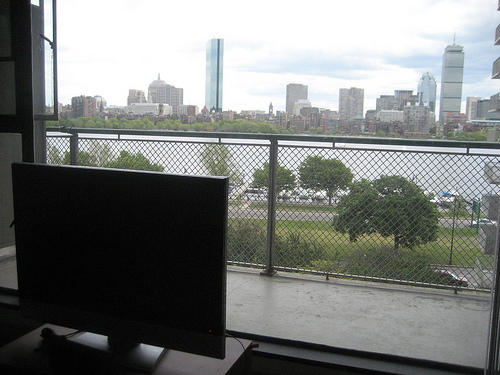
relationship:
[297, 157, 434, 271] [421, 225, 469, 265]
tree growing out of grass grass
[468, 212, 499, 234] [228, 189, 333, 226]
car on roads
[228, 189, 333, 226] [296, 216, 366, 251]
roads between lawns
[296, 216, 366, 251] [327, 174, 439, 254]
lawns between tree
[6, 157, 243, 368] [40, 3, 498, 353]
screen by window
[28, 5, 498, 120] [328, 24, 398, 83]
sky has clouds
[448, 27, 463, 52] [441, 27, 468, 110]
pole on top of building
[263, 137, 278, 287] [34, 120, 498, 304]
pole holding up fence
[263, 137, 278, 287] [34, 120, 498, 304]
pole supporting fence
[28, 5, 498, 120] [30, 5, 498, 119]
sky has clouds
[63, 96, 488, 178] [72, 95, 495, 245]
tree lining edge of river